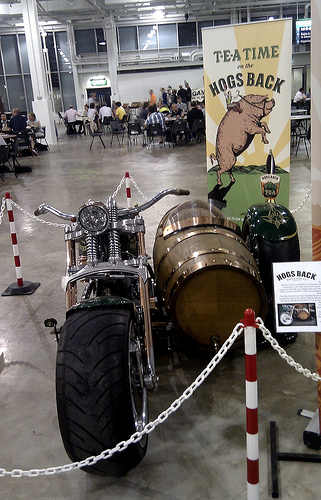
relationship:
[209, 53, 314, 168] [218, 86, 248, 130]
drawing of man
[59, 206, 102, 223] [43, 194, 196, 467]
headlight on motorcycle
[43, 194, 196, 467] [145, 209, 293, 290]
motorcycle has sidecar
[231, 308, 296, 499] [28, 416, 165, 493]
pole has chains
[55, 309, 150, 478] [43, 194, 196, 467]
tire on motorcycle